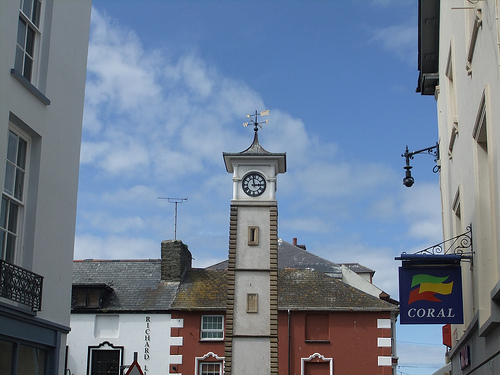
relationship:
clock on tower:
[239, 171, 267, 197] [218, 99, 287, 372]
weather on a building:
[72, 0, 442, 305] [74, 89, 403, 371]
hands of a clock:
[242, 169, 263, 196] [239, 171, 267, 197]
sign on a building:
[397, 257, 465, 329] [398, 2, 482, 372]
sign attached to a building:
[397, 257, 465, 329] [412, 1, 482, 372]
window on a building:
[200, 314, 225, 342] [5, 0, 103, 370]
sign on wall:
[397, 257, 465, 329] [420, 6, 479, 369]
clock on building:
[239, 171, 267, 197] [74, 89, 403, 371]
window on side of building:
[200, 314, 225, 342] [0, 0, 88, 370]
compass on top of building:
[237, 104, 267, 137] [79, 244, 395, 374]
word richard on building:
[144, 315, 152, 361] [79, 244, 395, 374]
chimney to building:
[153, 190, 201, 282] [79, 244, 395, 374]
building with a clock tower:
[79, 244, 395, 374] [242, 166, 268, 196]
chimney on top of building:
[159, 239, 192, 281] [79, 244, 395, 374]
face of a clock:
[240, 176, 267, 193] [239, 171, 267, 197]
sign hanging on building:
[397, 257, 465, 329] [391, 12, 498, 373]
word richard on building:
[132, 313, 160, 363] [79, 244, 395, 374]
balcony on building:
[109, 293, 406, 318] [79, 244, 395, 374]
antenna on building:
[153, 188, 196, 248] [79, 244, 395, 374]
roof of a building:
[83, 239, 203, 318] [79, 244, 395, 374]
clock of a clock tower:
[239, 171, 267, 197] [222, 108, 287, 375]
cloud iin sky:
[169, 53, 216, 106] [90, 51, 427, 273]